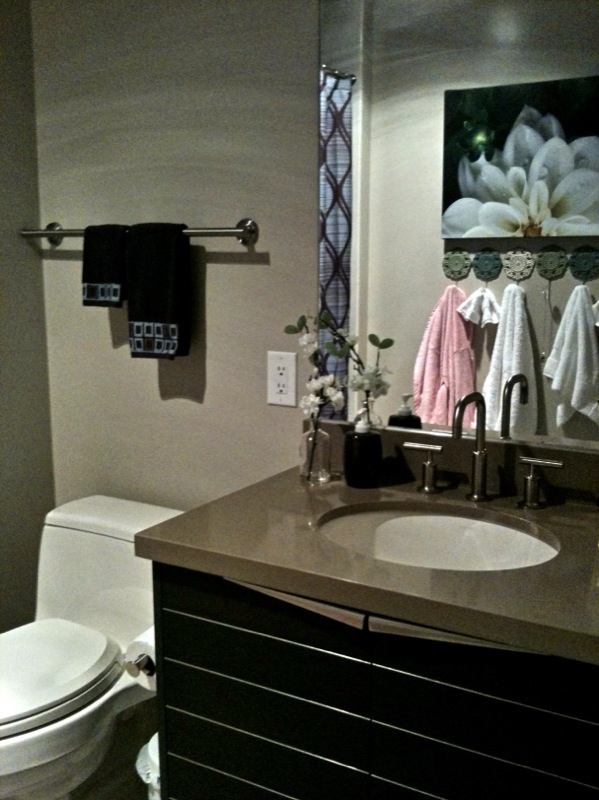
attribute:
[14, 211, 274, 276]
rack — towel rack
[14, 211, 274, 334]
towels — brown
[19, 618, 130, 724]
lid — down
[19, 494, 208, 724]
toilet — white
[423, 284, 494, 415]
towel — pink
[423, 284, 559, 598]
sink — bathroom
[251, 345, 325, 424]
outlet — electrical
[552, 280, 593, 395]
towel — white, hanging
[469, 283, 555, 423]
towel — hanging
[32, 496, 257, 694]
toilet — white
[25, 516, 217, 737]
toilet — white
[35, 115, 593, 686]
bathroom — white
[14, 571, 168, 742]
toilet — white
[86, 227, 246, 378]
towel — cotton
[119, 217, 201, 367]
towel — cotton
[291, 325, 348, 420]
flowers — white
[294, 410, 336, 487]
jar — clear, glass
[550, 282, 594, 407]
towel — cotton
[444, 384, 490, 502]
faucet — modern style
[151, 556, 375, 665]
drawers — black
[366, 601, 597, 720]
drawers — black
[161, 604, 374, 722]
drawers — black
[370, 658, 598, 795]
drawers — black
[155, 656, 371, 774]
drawers — black, gray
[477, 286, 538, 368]
towel — cotton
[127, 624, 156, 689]
tissue — white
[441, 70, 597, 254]
picture — decorative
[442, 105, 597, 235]
flower — white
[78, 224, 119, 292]
towel — cotton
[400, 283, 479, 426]
towel — cotton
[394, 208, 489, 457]
towels — white, black, hand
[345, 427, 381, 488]
black bottle — soap, white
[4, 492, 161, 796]
toilet — modern, white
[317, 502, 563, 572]
sink — bathroom, under-counter